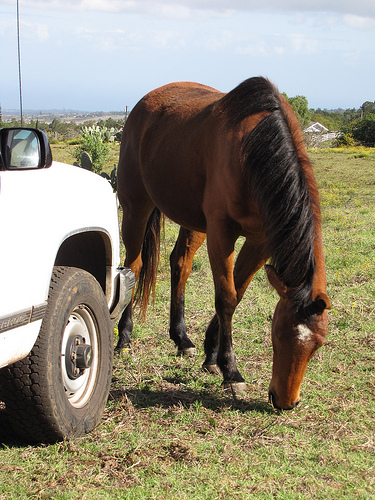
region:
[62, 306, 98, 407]
a white rim from a truck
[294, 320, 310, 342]
a white patch on a horses head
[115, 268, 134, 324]
chrome front bumper on front of truck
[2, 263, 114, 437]
Black rubber tire on truck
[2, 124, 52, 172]
black passenger side mirror on truck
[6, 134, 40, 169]
reflection image on side mirror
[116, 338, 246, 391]
hooves of a horse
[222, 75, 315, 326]
black mane on brown horse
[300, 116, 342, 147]
A house in the distance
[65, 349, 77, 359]
a lug nut on a truck tire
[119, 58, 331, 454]
brown horse eating grass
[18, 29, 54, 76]
white clouds in blue sky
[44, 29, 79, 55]
white clouds in blue sky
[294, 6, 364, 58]
white clouds in blue sky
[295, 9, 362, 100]
white clouds in blue sky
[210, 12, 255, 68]
white clouds in blue sky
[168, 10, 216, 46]
white clouds in blue sky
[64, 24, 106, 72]
white clouds in blue sky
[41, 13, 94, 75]
white clouds in blue sky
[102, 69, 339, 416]
A horse eating grass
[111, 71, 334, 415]
A horse eating grass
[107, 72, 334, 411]
A horse eating grass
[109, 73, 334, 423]
A horse eating grass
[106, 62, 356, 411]
A brownish red horse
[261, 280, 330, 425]
Horses head with white mark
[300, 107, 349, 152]
A house in the background on right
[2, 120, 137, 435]
A white truck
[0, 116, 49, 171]
A mirror on right side of truck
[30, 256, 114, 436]
A black tire on truck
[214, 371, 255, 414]
A grey horses hoof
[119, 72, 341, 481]
A horse eating grass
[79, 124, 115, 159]
A bush with white flowers